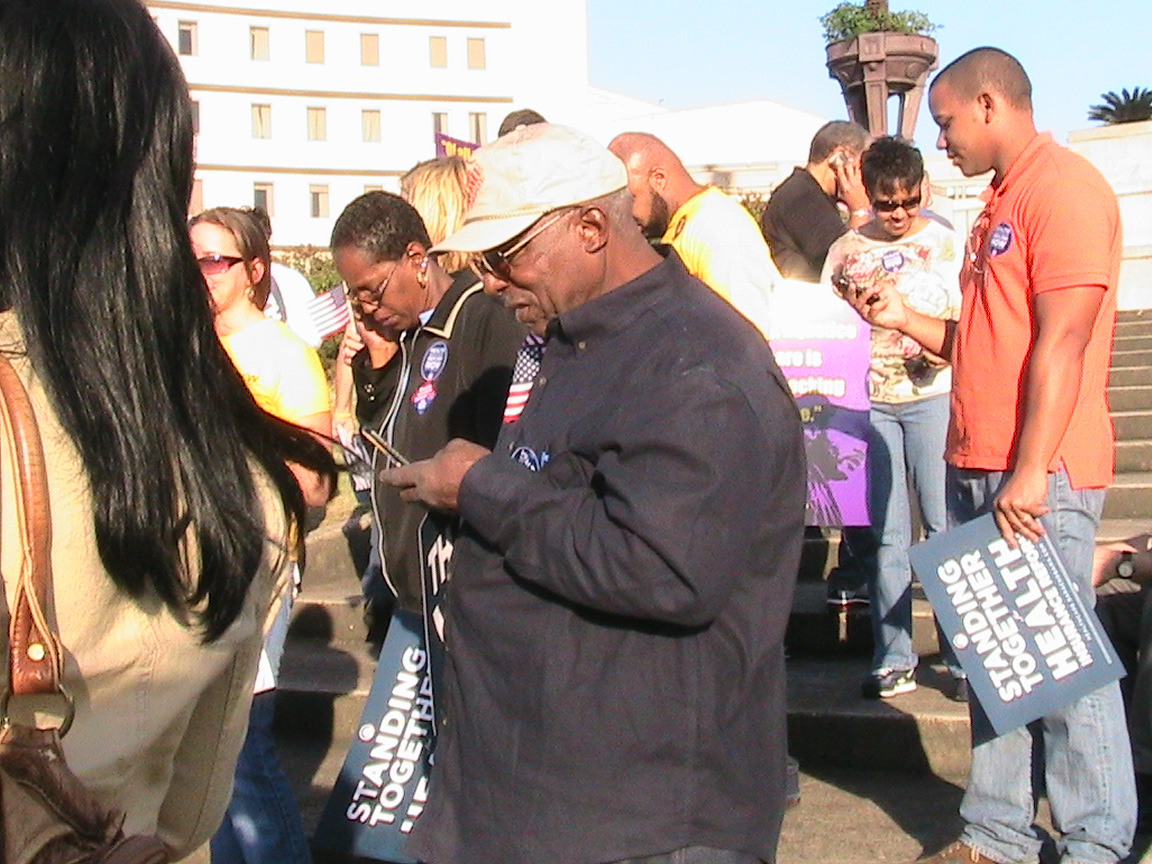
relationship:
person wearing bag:
[4, 6, 322, 860] [5, 357, 185, 859]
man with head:
[601, 117, 781, 359] [607, 119, 682, 244]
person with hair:
[4, 6, 322, 860] [2, 6, 366, 651]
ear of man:
[574, 203, 608, 254] [369, 125, 810, 855]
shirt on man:
[943, 126, 1131, 503] [825, 37, 1143, 860]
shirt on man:
[943, 126, 1131, 503] [903, 50, 1143, 860]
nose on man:
[461, 260, 519, 314] [369, 125, 810, 855]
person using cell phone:
[369, 113, 810, 860] [348, 423, 410, 473]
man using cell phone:
[825, 37, 1143, 860] [832, 264, 892, 316]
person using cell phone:
[369, 113, 810, 860] [356, 416, 425, 470]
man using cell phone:
[835, 44, 1142, 864] [825, 257, 898, 307]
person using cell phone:
[369, 113, 810, 860] [354, 421, 418, 471]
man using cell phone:
[835, 44, 1142, 864] [836, 253, 892, 307]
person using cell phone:
[369, 113, 810, 860] [337, 410, 410, 470]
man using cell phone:
[835, 44, 1142, 864] [838, 257, 898, 321]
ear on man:
[976, 75, 1001, 118] [825, 37, 1143, 860]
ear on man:
[568, 194, 616, 263] [369, 125, 810, 855]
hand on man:
[360, 433, 498, 527] [369, 125, 810, 855]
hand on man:
[838, 270, 925, 351] [825, 37, 1143, 860]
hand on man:
[993, 467, 1057, 552] [825, 37, 1143, 860]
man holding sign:
[835, 44, 1142, 864] [896, 492, 1128, 741]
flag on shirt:
[484, 339, 557, 445] [447, 333, 639, 747]